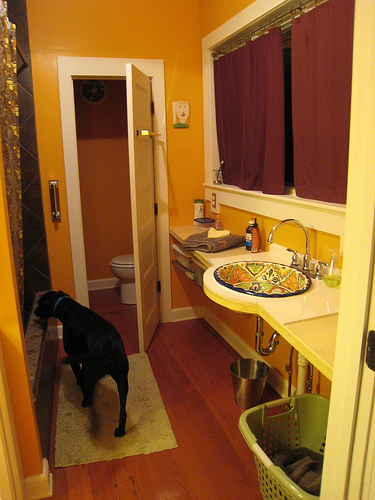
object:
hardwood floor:
[183, 373, 208, 458]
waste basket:
[237, 393, 330, 500]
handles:
[285, 248, 300, 266]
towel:
[181, 226, 246, 253]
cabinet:
[282, 312, 337, 370]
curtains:
[290, 0, 354, 205]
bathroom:
[0, 0, 375, 500]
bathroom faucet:
[266, 217, 311, 273]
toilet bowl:
[109, 253, 136, 305]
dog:
[32, 290, 130, 438]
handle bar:
[48, 179, 60, 221]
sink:
[213, 260, 312, 296]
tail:
[119, 357, 129, 398]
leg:
[112, 370, 129, 429]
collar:
[54, 295, 69, 305]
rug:
[54, 350, 178, 470]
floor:
[146, 317, 234, 412]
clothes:
[271, 446, 322, 495]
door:
[125, 62, 162, 354]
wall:
[136, 21, 183, 64]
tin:
[229, 358, 269, 410]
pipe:
[255, 316, 280, 357]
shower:
[19, 76, 37, 299]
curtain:
[0, 16, 23, 319]